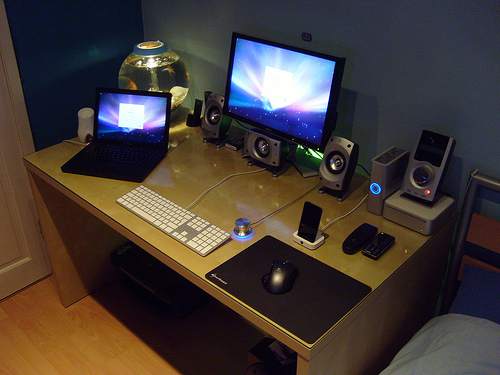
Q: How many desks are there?
A: One.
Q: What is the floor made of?
A: Wood.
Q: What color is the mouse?
A: Black.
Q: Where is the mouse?
A: On the mouse pad.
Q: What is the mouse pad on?
A: The desk.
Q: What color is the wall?
A: Blue.